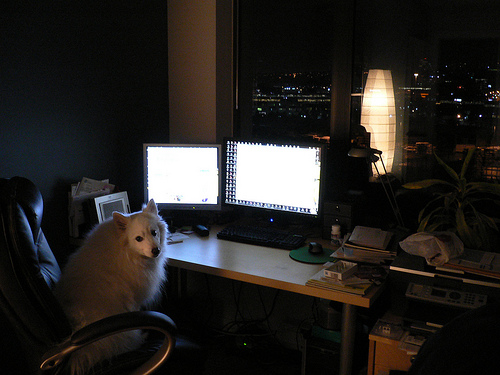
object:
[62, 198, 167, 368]
chair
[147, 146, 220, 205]
monitor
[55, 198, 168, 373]
desk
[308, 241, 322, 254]
mouse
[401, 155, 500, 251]
plant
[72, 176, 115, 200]
paper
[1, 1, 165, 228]
wall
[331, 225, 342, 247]
bottle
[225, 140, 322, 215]
monitors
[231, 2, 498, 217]
window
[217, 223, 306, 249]
keyboard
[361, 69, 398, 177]
lamp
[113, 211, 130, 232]
ear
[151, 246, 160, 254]
nose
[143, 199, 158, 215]
ear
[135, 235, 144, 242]
eye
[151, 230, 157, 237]
eye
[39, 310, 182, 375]
arm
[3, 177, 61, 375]
back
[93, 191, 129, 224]
papers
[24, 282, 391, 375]
frame